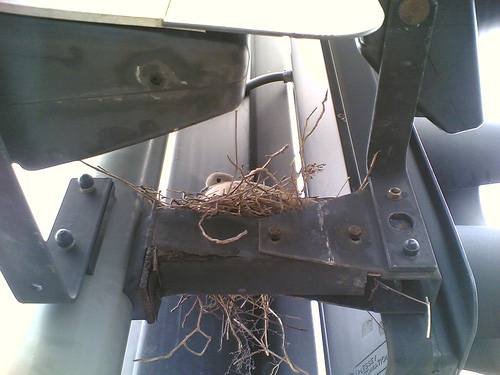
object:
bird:
[198, 170, 279, 198]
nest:
[134, 149, 320, 218]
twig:
[292, 87, 331, 207]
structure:
[0, 211, 497, 323]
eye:
[215, 178, 220, 185]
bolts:
[54, 227, 77, 252]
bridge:
[317, 25, 481, 374]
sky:
[481, 37, 498, 117]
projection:
[2, 0, 385, 41]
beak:
[196, 185, 213, 195]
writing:
[343, 341, 400, 375]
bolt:
[402, 236, 420, 256]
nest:
[167, 294, 304, 362]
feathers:
[222, 181, 279, 196]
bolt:
[386, 185, 404, 200]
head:
[199, 171, 235, 191]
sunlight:
[32, 172, 55, 216]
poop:
[306, 195, 339, 266]